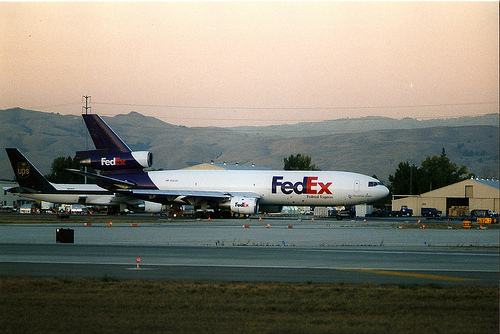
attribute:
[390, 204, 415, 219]
truck — parked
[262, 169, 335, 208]
name — company's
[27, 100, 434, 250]
aircraft — parked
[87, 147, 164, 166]
engine — large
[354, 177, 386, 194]
cockpit — plane's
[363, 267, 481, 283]
line — yellow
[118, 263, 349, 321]
grass — green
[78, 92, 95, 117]
pole — large, metal, electric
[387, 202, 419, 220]
truck — work, parked